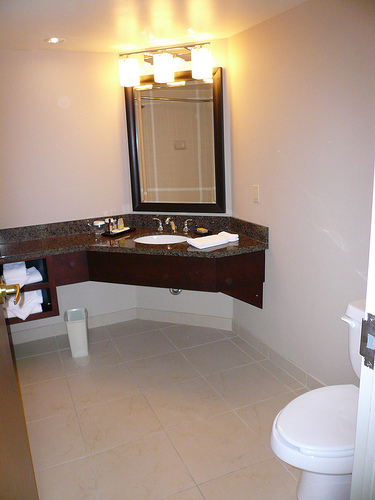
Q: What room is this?
A: Bathroom.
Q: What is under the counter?
A: Trash can.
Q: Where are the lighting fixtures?
A: Over the mirror.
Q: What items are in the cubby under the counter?
A: Towels.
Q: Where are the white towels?
A: Under the sink.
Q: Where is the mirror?
A: On the wall under the lights.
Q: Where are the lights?
A: Above the mirror.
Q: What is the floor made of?
A: Tiles.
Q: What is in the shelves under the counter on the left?
A: Towels.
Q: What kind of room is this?
A: Bathroom.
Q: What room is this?
A: Bathroom.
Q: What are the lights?
A: Over the mirror.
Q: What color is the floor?
A: Off white.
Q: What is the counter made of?
A: Marble.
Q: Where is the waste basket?
A: Under the sink.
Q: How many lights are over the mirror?
A: 3.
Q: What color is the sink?
A: White.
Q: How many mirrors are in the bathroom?
A: 1.